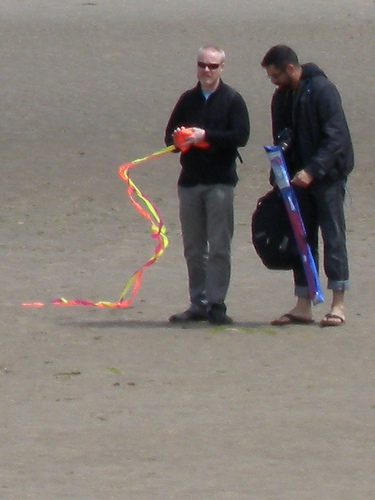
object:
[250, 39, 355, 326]
man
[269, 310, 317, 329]
sandal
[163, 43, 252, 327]
man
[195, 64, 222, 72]
sunglasses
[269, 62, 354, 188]
jacket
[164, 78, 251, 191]
sweater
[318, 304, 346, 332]
foot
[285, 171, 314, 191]
hand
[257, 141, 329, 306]
object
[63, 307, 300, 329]
shadow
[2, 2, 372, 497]
ground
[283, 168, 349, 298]
pants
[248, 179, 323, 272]
backpack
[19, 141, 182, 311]
ribbon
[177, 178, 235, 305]
slacks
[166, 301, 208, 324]
sock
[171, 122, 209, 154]
toy